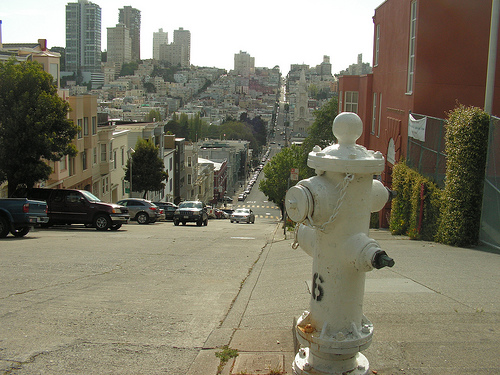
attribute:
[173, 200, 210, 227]
suv —   black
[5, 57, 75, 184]
tree —  large,  green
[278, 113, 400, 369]
hydrant —  white, for fire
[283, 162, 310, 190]
traffic sign —  red and white, for traffic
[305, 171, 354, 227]
chain —  white